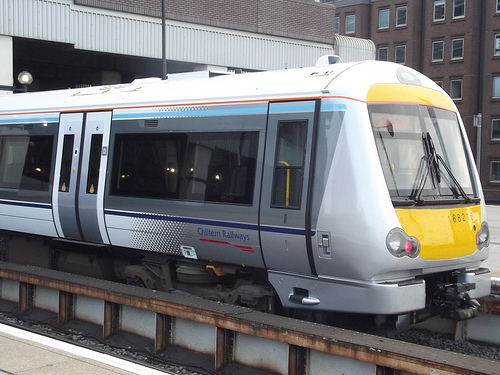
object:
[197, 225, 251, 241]
writing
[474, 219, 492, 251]
light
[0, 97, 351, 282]
side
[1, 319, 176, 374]
platform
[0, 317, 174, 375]
station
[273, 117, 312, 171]
window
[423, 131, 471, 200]
wipers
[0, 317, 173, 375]
line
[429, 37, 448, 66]
window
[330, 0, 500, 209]
building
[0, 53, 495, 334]
train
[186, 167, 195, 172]
glare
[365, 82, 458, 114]
yellow paint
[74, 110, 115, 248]
door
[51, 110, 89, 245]
door